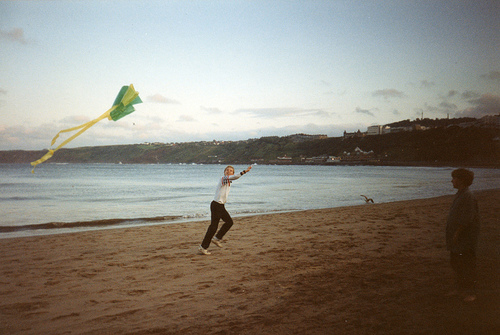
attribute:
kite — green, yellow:
[28, 84, 141, 173]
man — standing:
[198, 162, 264, 256]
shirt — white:
[211, 168, 248, 206]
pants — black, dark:
[200, 200, 234, 249]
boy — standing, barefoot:
[442, 168, 482, 303]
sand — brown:
[0, 187, 498, 334]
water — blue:
[1, 162, 499, 238]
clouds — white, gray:
[0, 22, 499, 150]